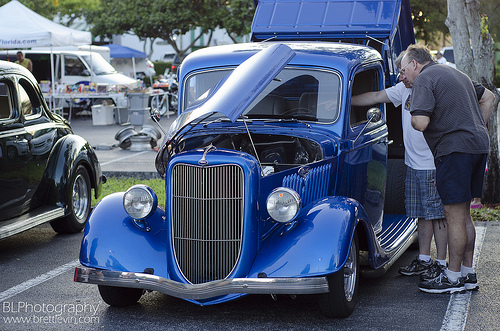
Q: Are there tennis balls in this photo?
A: No, there are no tennis balls.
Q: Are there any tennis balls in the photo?
A: No, there are no tennis balls.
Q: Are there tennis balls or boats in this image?
A: No, there are no tennis balls or boats.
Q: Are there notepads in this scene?
A: No, there are no notepads.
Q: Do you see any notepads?
A: No, there are no notepads.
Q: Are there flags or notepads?
A: No, there are no notepads or flags.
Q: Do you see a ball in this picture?
A: No, there are no balls.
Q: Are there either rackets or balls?
A: No, there are no balls or rackets.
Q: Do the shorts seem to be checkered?
A: Yes, the shorts are checkered.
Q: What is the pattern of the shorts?
A: The shorts are checkered.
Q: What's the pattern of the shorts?
A: The shorts are checkered.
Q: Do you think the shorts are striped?
A: No, the shorts are checkered.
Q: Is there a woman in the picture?
A: No, there are no women.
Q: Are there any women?
A: No, there are no women.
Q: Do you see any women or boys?
A: No, there are no women or boys.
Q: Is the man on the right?
A: Yes, the man is on the right of the image.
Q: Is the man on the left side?
A: No, the man is on the right of the image.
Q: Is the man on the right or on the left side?
A: The man is on the right of the image.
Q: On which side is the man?
A: The man is on the right of the image.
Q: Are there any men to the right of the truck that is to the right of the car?
A: Yes, there is a man to the right of the truck.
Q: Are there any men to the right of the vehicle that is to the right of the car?
A: Yes, there is a man to the right of the truck.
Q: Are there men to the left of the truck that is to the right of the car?
A: No, the man is to the right of the truck.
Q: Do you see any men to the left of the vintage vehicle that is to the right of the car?
A: No, the man is to the right of the truck.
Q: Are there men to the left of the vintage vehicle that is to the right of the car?
A: No, the man is to the right of the truck.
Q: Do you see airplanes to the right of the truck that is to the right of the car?
A: No, there is a man to the right of the truck.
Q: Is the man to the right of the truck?
A: Yes, the man is to the right of the truck.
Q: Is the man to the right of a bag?
A: No, the man is to the right of the truck.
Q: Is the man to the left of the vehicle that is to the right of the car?
A: No, the man is to the right of the truck.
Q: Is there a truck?
A: Yes, there is a truck.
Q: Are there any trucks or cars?
A: Yes, there is a truck.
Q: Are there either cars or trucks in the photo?
A: Yes, there is a truck.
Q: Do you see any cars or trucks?
A: Yes, there is a truck.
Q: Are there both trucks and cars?
A: Yes, there are both a truck and a car.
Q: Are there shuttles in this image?
A: No, there are no shuttles.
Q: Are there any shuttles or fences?
A: No, there are no shuttles or fences.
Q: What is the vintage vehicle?
A: The vehicle is a truck.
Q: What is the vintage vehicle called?
A: The vehicle is a truck.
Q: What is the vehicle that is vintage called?
A: The vehicle is a truck.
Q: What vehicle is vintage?
A: The vehicle is a truck.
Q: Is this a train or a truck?
A: This is a truck.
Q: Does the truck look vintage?
A: Yes, the truck is vintage.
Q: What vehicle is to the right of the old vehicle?
A: The vehicle is a truck.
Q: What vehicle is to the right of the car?
A: The vehicle is a truck.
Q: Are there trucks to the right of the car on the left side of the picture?
A: Yes, there is a truck to the right of the car.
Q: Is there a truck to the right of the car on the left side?
A: Yes, there is a truck to the right of the car.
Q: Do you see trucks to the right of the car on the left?
A: Yes, there is a truck to the right of the car.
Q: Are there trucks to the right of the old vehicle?
A: Yes, there is a truck to the right of the car.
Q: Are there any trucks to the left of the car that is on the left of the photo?
A: No, the truck is to the right of the car.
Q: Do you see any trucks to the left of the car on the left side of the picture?
A: No, the truck is to the right of the car.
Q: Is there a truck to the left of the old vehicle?
A: No, the truck is to the right of the car.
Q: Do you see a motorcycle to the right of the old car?
A: No, there is a truck to the right of the car.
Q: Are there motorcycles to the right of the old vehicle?
A: No, there is a truck to the right of the car.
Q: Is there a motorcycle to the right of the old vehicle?
A: No, there is a truck to the right of the car.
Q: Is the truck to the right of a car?
A: Yes, the truck is to the right of a car.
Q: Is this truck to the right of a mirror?
A: No, the truck is to the right of a car.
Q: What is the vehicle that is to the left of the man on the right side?
A: The vehicle is a truck.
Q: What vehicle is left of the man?
A: The vehicle is a truck.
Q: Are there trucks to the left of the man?
A: Yes, there is a truck to the left of the man.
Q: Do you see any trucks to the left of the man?
A: Yes, there is a truck to the left of the man.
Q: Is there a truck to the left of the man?
A: Yes, there is a truck to the left of the man.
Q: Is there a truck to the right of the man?
A: No, the truck is to the left of the man.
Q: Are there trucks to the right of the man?
A: No, the truck is to the left of the man.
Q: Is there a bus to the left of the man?
A: No, there is a truck to the left of the man.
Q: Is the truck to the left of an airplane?
A: No, the truck is to the left of a man.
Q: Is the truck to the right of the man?
A: No, the truck is to the left of the man.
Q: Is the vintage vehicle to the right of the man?
A: No, the truck is to the left of the man.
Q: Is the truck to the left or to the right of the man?
A: The truck is to the left of the man.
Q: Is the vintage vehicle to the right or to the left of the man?
A: The truck is to the left of the man.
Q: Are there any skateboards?
A: No, there are no skateboards.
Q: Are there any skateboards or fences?
A: No, there are no skateboards or fences.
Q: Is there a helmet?
A: No, there are no helmets.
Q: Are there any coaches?
A: No, there are no coaches.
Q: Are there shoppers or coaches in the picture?
A: No, there are no coaches or shoppers.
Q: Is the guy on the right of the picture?
A: Yes, the guy is on the right of the image.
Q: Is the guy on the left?
A: No, the guy is on the right of the image.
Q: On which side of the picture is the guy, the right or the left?
A: The guy is on the right of the image.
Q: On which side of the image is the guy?
A: The guy is on the right of the image.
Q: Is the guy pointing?
A: Yes, the guy is pointing.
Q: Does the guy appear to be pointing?
A: Yes, the guy is pointing.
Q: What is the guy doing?
A: The guy is pointing.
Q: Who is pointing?
A: The guy is pointing.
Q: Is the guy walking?
A: No, the guy is pointing.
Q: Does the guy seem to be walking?
A: No, the guy is pointing.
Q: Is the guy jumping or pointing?
A: The guy is pointing.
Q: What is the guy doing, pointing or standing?
A: The guy is pointing.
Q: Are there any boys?
A: No, there are no boys.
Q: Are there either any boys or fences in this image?
A: No, there are no boys or fences.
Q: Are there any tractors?
A: No, there are no tractors.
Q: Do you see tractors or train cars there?
A: No, there are no tractors or train cars.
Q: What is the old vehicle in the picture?
A: The vehicle is a car.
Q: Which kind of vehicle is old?
A: The vehicle is a car.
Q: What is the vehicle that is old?
A: The vehicle is a car.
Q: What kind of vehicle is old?
A: The vehicle is a car.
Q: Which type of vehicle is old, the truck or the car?
A: The car is old.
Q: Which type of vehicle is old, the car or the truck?
A: The car is old.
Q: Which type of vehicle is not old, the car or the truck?
A: The truck is not old.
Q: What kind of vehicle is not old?
A: The vehicle is a truck.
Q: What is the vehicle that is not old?
A: The vehicle is a truck.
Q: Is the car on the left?
A: Yes, the car is on the left of the image.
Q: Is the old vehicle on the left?
A: Yes, the car is on the left of the image.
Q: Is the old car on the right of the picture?
A: No, the car is on the left of the image.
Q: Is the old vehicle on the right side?
A: No, the car is on the left of the image.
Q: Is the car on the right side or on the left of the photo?
A: The car is on the left of the image.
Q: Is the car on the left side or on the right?
A: The car is on the left of the image.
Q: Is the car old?
A: Yes, the car is old.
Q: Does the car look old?
A: Yes, the car is old.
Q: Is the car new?
A: No, the car is old.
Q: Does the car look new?
A: No, the car is old.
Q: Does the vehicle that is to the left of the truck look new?
A: No, the car is old.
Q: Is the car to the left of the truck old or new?
A: The car is old.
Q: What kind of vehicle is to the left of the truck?
A: The vehicle is a car.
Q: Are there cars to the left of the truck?
A: Yes, there is a car to the left of the truck.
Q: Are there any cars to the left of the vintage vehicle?
A: Yes, there is a car to the left of the truck.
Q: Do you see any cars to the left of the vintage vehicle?
A: Yes, there is a car to the left of the truck.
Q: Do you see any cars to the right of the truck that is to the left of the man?
A: No, the car is to the left of the truck.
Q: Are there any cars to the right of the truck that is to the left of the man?
A: No, the car is to the left of the truck.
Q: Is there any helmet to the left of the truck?
A: No, there is a car to the left of the truck.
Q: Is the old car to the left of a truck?
A: Yes, the car is to the left of a truck.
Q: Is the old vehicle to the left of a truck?
A: Yes, the car is to the left of a truck.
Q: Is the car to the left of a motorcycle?
A: No, the car is to the left of a truck.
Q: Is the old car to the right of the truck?
A: No, the car is to the left of the truck.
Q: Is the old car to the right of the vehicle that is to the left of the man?
A: No, the car is to the left of the truck.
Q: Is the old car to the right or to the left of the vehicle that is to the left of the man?
A: The car is to the left of the truck.